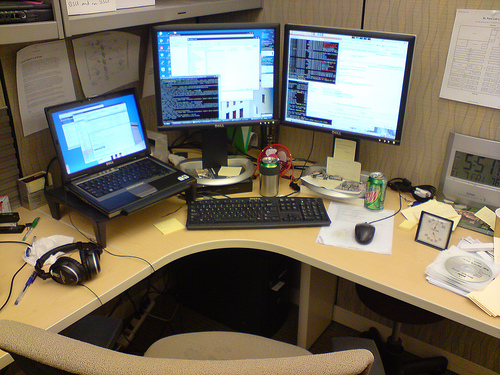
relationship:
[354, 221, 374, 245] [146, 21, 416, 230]
mouse of computer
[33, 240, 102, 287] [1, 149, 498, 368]
headphone on desk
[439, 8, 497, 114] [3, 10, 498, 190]
paper on wall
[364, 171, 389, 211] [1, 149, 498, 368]
can over desk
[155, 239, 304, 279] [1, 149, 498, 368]
curve edge of desk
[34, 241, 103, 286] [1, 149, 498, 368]
headphone laying on desk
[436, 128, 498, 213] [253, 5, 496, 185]
clock against wall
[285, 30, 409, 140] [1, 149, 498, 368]
computer screen on desk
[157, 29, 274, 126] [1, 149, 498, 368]
computer screen on desk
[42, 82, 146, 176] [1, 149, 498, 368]
screen on desk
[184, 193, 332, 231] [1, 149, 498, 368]
keyboard on desk